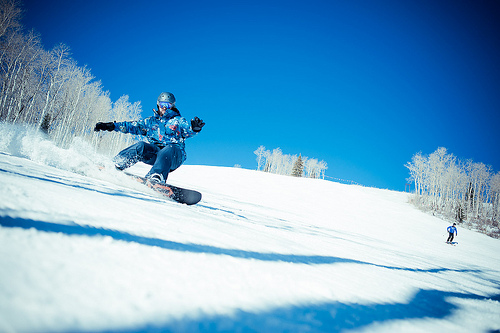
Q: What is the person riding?
A: A snowboard.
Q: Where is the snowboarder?
A: On a slope.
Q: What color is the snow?
A: White.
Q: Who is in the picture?
A: A snowboarder.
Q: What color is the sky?
A: Blue.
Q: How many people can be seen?
A: 2.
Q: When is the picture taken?
A: Daytime.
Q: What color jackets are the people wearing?
A: Blue.